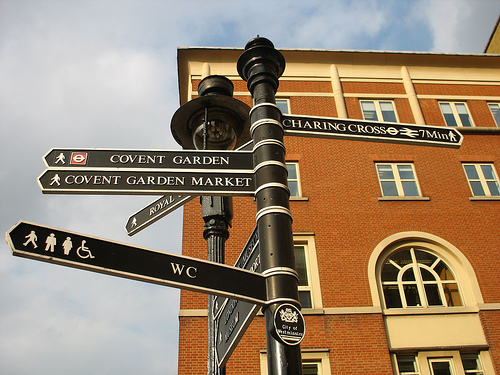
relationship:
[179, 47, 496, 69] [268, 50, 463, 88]
roof soffit and edge of shingles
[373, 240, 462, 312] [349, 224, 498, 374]
mullions in window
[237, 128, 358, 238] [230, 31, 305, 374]
city marker on pole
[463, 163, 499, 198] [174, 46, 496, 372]
window on building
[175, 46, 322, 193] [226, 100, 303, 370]
sign on side of pole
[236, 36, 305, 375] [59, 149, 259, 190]
pole with street signs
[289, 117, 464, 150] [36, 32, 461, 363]
charing cross street sign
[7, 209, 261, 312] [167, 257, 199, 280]
sign guiding you to wc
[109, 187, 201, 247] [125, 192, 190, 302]
partial sign to royal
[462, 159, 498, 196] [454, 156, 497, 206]
window of  paned glass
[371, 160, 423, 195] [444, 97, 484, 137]
window of  paned glass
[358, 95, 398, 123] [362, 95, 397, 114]
window of  paned glass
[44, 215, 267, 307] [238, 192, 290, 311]
sign on pole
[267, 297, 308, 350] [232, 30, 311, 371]
sign on front of pole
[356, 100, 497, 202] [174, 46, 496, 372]
windows on front of building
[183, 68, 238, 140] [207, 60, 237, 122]
top of street light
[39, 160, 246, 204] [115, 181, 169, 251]
arrow for directions to covent garden market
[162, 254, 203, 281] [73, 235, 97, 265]
wc capable for someone in a wheelchair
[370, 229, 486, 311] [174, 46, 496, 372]
window in middle of building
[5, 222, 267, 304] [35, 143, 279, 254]
sign are very helpful